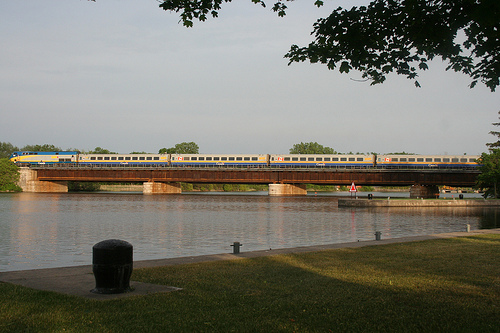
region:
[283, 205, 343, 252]
A still water surface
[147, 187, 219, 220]
A still water surface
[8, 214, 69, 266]
A still water surface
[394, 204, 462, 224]
A still water surface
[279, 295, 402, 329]
A green grass surface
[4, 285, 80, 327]
A green grass surface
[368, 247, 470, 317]
A green grass surface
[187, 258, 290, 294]
A green grass surface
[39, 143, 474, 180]
A train truck bridge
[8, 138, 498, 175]
train on the track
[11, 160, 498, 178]
track elevated above water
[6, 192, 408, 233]
water beneath the track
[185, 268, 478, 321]
grass in the park area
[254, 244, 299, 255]
concrete edge near grass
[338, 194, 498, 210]
concrete strip near rail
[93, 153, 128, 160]
windows on the train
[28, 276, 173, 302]
concrete square in grass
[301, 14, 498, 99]
branches hanging from trees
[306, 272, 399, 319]
green color grass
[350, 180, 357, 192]
sign board with white and red color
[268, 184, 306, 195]
pillar supporting bridge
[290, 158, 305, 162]
windows of train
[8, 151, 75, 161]
engine of the train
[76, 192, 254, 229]
water running from the bridge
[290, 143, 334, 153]
trees visible from background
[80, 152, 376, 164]
bogies of train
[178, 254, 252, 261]
grey color pavement created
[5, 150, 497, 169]
Train moving on the bridge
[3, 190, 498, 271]
River under the bridge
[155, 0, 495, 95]
Leaves of a tree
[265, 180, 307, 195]
Support of the bridge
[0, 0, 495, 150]
Cloudy weather in the sky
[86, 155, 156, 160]
Windows of the train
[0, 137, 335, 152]
Greent trees near the train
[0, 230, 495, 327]
Green grass area near the river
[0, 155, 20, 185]
Green foliage near the train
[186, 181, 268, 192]
Green shrub near the river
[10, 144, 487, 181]
the train on the bridge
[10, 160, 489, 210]
the bridge over the water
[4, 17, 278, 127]
the sky is blue and clear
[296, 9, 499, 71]
the branches with leaves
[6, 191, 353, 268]
the water is calm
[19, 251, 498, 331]
the grass beside the water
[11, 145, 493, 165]
the train is blue and gray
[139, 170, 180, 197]
the column supporting the bridge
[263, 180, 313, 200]
the column supporting the bridge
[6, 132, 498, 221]
there is a train on the tracks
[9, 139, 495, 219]
this bridge crosses a river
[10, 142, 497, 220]
the train is traveling on the bridge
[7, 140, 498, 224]
the train is going across the river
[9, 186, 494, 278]
this is a river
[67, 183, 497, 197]
water under the bridge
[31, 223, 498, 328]
this is a path walk on the side of a river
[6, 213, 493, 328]
this is the shoreline of a river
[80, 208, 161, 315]
this is a trashcan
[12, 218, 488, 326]
the lawn is shaded by the tree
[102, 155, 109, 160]
passenger window of a passenger train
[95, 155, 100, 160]
passenger window of a passenger train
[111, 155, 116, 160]
passenger window of a passenger train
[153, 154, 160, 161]
passenger window of a passenger train